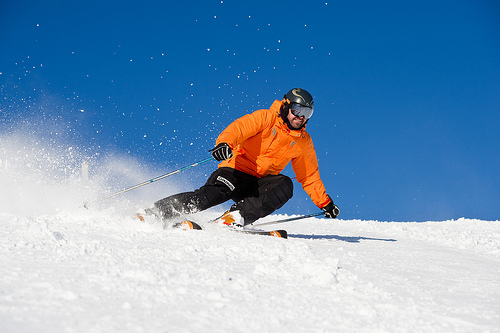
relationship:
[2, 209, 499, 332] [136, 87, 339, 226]
hill has a skier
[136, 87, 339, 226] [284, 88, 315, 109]
skier has helmet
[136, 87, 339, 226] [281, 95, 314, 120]
skier wearing goggles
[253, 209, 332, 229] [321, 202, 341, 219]
pole held by left hand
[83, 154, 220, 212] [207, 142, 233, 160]
pole held by right hand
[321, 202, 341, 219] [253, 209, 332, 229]
left hand holding pole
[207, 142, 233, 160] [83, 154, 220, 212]
right hand hold pole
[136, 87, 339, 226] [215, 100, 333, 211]
skier has a coat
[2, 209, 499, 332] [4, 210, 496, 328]
hill has snow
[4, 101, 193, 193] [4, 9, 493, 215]
snow in air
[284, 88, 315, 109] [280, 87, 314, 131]
helmet on head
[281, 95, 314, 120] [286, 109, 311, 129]
goggles on mans face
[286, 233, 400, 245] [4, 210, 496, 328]
shadow on snow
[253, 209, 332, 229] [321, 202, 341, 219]
pole in left hand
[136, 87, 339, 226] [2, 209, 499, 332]
man going down hill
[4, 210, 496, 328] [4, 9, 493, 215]
snow in air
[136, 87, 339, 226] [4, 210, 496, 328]
skier in snow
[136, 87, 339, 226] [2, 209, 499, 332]
skier going down hill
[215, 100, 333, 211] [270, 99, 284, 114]
coat has a hood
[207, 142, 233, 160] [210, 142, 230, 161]
right hand has glove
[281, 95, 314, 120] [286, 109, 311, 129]
goggles on face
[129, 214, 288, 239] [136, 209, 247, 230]
skies on feet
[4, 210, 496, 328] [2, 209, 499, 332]
snow on hill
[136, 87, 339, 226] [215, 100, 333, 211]
skier has an orange coat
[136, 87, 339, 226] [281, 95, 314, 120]
skier has goggles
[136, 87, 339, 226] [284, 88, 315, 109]
skier has a helmet